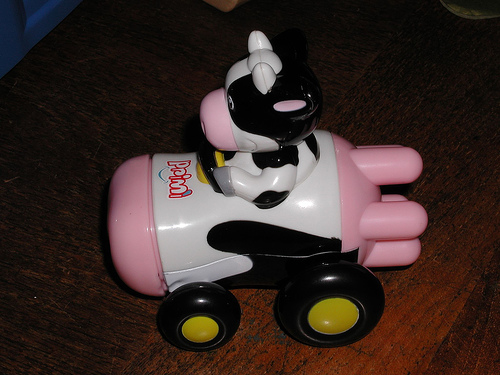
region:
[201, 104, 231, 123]
Cow has pink nose.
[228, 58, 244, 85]
Cow has white spot on head.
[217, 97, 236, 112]
Cow has black eye.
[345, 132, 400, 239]
Cow car has pink utters.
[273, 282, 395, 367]
Black wheel on car.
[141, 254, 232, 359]
Black wheel on car.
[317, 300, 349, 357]
Yellow middle section on car.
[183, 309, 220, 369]
Yellow middle section on tire.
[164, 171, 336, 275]
Cow car has markings just like the cow.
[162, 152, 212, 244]
Red writing on front of car.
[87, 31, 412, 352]
small tow on table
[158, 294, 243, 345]
small black front wheel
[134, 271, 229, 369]
black and yellow wheel of toy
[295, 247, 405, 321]
large black back wheel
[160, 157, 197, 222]
logo on front of toy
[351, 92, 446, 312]
pink utters on toy back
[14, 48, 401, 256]
cow driving a toy car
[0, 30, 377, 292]
toy cow driving a cow car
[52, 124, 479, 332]
car in the shape of utters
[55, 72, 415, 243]
pink and white toy car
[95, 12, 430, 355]
this is a toy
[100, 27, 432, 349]
the toy is pink, black and white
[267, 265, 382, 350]
the wheel of a toy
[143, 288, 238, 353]
the wheel of a toy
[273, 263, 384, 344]
the wheel of a toy is black and yellow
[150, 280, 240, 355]
the wheel of a toy is black and yellow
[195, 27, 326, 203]
the driver of the toy car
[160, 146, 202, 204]
writing on the toy car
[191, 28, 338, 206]
the driver of the toy car is piggy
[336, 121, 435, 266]
the rear area is pink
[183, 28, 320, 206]
black and white toy cow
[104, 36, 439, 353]
A cow themed child's toy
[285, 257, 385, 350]
The toy's larger back tire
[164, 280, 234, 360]
The toy's smaller front tire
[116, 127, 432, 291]
A toy vehicle shaped like an utter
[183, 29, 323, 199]
A toy cow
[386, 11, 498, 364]
Wooden surface below the toy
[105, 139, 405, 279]
The toy is black, white, and pink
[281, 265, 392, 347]
The tires are black and yellow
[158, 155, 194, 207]
The toy says "Ppimi"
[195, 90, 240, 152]
The cow's nose is pink